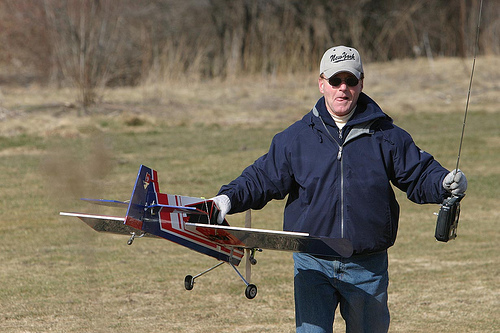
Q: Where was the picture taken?
A: In a field.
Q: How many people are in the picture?
A: One.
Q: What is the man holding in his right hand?
A: A remote controlled airplane.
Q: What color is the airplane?
A: Red, white and blue.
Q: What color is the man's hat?
A: Gray.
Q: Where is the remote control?
A: The man's left hand.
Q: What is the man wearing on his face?
A: Sunglasses.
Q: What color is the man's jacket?
A: Blue.